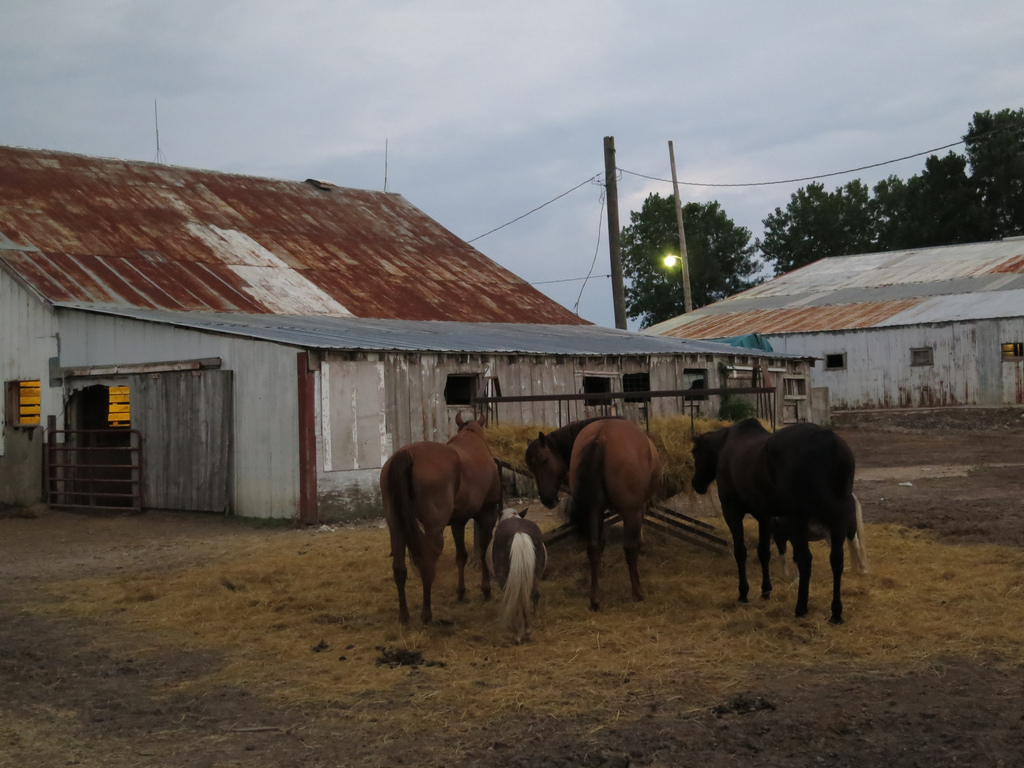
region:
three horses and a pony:
[375, 411, 879, 643]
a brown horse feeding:
[383, 392, 495, 633]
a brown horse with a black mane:
[529, 418, 662, 608]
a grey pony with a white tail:
[488, 502, 555, 638]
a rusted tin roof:
[5, 143, 590, 324]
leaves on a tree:
[624, 183, 754, 317]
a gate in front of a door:
[42, 414, 151, 517]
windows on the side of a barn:
[333, 366, 733, 423]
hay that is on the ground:
[80, 533, 1010, 721]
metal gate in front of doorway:
[41, 416, 149, 512]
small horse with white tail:
[480, 499, 550, 642]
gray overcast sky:
[2, 2, 1023, 328]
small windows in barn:
[438, 366, 726, 412]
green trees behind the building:
[615, 104, 1023, 324]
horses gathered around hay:
[360, 407, 885, 643]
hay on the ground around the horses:
[59, 505, 1023, 724]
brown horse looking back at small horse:
[528, 411, 659, 614]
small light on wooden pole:
[659, 253, 691, 269]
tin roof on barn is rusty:
[0, 143, 825, 521]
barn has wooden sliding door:
[1, 149, 831, 533]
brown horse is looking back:
[521, 405, 670, 611]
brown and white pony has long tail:
[488, 478, 556, 655]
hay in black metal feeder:
[466, 376, 783, 598]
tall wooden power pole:
[590, 128, 633, 332]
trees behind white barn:
[615, 114, 1021, 413]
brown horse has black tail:
[372, 411, 519, 637]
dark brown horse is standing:
[681, 418, 874, 638]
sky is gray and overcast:
[1, 1, 1022, 344]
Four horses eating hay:
[332, 335, 902, 740]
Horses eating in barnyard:
[349, 351, 913, 700]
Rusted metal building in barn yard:
[2, 140, 901, 570]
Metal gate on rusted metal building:
[1, 336, 276, 546]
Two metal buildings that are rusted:
[0, 111, 1015, 538]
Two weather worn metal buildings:
[0, 118, 1016, 549]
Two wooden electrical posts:
[561, 102, 697, 341]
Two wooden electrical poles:
[564, 111, 714, 339]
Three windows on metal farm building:
[806, 329, 1016, 387]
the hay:
[585, 611, 709, 692]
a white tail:
[505, 539, 540, 615]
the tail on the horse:
[500, 542, 548, 628]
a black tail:
[379, 459, 424, 539]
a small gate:
[54, 424, 134, 502]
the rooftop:
[331, 242, 433, 284]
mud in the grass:
[784, 702, 880, 745]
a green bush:
[689, 220, 753, 290]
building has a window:
[438, 375, 481, 402]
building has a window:
[618, 375, 647, 402]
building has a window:
[688, 372, 708, 401]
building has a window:
[823, 350, 849, 367]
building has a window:
[911, 349, 935, 375]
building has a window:
[1001, 341, 1022, 358]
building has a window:
[14, 381, 44, 432]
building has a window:
[69, 384, 139, 518]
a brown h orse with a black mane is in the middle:
[529, 412, 665, 615]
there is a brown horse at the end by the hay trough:
[361, 415, 502, 625]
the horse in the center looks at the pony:
[523, 408, 667, 609]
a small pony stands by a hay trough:
[488, 503, 546, 639]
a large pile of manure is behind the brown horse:
[306, 639, 450, 681]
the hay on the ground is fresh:
[65, 506, 1021, 687]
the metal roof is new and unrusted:
[56, 303, 819, 361]